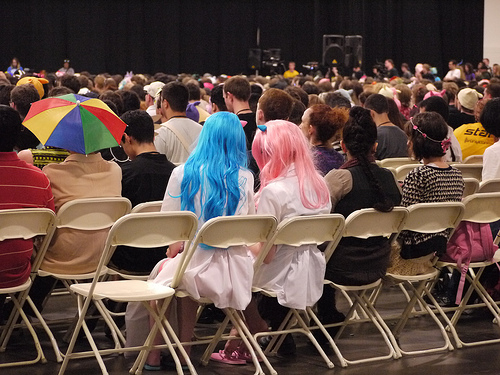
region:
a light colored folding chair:
[55, 211, 202, 373]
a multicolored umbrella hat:
[22, 88, 133, 155]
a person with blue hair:
[161, 112, 251, 297]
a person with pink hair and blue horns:
[250, 115, 331, 298]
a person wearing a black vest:
[317, 106, 404, 282]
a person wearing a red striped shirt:
[0, 102, 57, 292]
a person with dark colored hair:
[396, 115, 459, 277]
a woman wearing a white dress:
[146, 114, 263, 365]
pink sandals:
[205, 341, 262, 371]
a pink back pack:
[446, 197, 495, 310]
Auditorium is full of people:
[0, 31, 499, 366]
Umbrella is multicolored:
[21, 86, 133, 160]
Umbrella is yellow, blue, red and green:
[14, 82, 133, 159]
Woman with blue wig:
[150, 105, 260, 330]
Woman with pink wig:
[250, 110, 340, 315]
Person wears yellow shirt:
[278, 55, 303, 83]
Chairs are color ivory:
[2, 200, 497, 370]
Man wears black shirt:
[110, 101, 183, 277]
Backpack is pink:
[441, 205, 496, 310]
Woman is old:
[294, 97, 354, 177]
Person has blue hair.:
[191, 137, 255, 244]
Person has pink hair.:
[260, 167, 328, 217]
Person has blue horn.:
[251, 110, 279, 157]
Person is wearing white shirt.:
[156, 190, 276, 323]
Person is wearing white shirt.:
[279, 233, 319, 313]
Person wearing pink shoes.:
[219, 333, 236, 358]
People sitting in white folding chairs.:
[119, 229, 213, 371]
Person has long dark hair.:
[337, 120, 404, 245]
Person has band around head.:
[406, 112, 436, 167]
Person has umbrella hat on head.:
[28, 99, 166, 254]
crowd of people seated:
[87, 60, 462, 225]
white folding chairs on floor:
[94, 203, 410, 368]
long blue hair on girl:
[178, 109, 248, 236]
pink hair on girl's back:
[278, 117, 330, 212]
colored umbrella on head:
[21, 88, 134, 158]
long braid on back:
[351, 150, 393, 222]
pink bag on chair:
[440, 216, 490, 273]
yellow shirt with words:
[452, 116, 494, 155]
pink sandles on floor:
[207, 339, 268, 366]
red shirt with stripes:
[4, 161, 56, 218]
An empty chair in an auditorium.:
[57, 209, 202, 374]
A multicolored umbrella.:
[21, 92, 128, 155]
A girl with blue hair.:
[124, 111, 254, 371]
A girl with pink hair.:
[220, 119, 332, 355]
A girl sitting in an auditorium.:
[389, 112, 464, 275]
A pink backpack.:
[445, 219, 494, 304]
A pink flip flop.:
[207, 350, 247, 364]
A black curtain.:
[0, 0, 485, 77]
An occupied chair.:
[0, 207, 57, 367]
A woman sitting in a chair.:
[256, 106, 403, 356]